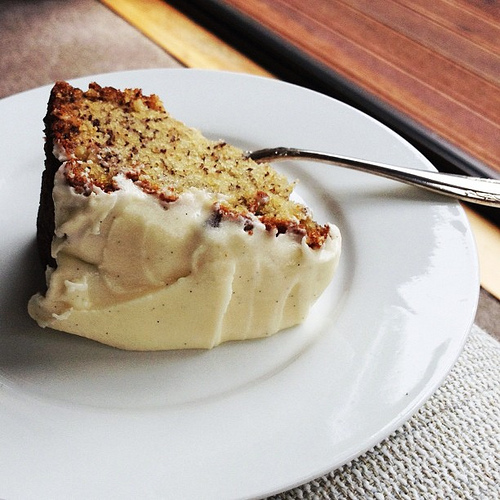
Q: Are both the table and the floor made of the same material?
A: Yes, both the table and the floor are made of wood.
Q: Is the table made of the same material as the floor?
A: Yes, both the table and the floor are made of wood.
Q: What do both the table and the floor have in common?
A: The material, both the table and the floor are wooden.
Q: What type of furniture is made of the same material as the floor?
A: The table is made of the same material as the floor.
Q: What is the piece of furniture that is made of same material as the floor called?
A: The piece of furniture is a table.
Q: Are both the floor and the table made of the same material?
A: Yes, both the floor and the table are made of wood.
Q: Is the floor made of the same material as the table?
A: Yes, both the floor and the table are made of wood.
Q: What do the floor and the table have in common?
A: The material, both the floor and the table are wooden.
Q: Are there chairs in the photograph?
A: No, there are no chairs.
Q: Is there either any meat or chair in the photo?
A: No, there are no chairs or meat.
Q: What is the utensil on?
A: The utensil is on the plate.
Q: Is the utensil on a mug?
A: No, the utensil is on the plate.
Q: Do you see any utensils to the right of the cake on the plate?
A: Yes, there is a utensil to the right of the cake.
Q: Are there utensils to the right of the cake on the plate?
A: Yes, there is a utensil to the right of the cake.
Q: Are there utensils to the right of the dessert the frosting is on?
A: Yes, there is a utensil to the right of the cake.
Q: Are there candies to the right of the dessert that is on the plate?
A: No, there is a utensil to the right of the cake.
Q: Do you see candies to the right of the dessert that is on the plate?
A: No, there is a utensil to the right of the cake.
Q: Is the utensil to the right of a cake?
A: Yes, the utensil is to the right of a cake.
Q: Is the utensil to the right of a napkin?
A: No, the utensil is to the right of a cake.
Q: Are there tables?
A: Yes, there is a table.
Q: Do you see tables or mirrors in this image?
A: Yes, there is a table.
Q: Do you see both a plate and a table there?
A: Yes, there are both a table and a plate.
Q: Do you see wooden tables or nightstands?
A: Yes, there is a wood table.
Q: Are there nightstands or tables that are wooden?
A: Yes, the table is wooden.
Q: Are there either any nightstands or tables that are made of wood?
A: Yes, the table is made of wood.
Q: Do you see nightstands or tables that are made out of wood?
A: Yes, the table is made of wood.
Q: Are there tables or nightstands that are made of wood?
A: Yes, the table is made of wood.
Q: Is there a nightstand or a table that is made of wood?
A: Yes, the table is made of wood.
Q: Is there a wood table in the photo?
A: Yes, there is a wood table.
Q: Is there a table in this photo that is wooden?
A: Yes, there is a table that is wooden.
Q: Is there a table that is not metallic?
A: Yes, there is a wooden table.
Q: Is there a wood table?
A: Yes, there is a table that is made of wood.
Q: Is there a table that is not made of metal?
A: Yes, there is a table that is made of wood.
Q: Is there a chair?
A: No, there are no chairs.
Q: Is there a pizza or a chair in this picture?
A: No, there are no chairs or pizzas.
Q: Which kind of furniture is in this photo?
A: The furniture is a table.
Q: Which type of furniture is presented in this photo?
A: The furniture is a table.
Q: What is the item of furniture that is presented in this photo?
A: The piece of furniture is a table.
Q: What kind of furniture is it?
A: The piece of furniture is a table.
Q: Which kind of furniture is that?
A: That is a table.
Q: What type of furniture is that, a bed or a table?
A: That is a table.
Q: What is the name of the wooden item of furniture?
A: The piece of furniture is a table.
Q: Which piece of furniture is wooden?
A: The piece of furniture is a table.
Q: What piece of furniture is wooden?
A: The piece of furniture is a table.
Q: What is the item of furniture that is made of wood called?
A: The piece of furniture is a table.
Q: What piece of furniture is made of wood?
A: The piece of furniture is a table.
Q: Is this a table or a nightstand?
A: This is a table.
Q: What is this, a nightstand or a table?
A: This is a table.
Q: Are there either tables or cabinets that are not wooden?
A: No, there is a table but it is wooden.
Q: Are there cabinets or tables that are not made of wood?
A: No, there is a table but it is made of wood.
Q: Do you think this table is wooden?
A: Yes, the table is wooden.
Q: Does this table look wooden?
A: Yes, the table is wooden.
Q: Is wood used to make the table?
A: Yes, the table is made of wood.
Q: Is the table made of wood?
A: Yes, the table is made of wood.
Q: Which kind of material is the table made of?
A: The table is made of wood.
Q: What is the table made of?
A: The table is made of wood.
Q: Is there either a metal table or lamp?
A: No, there is a table but it is wooden.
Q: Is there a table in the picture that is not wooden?
A: No, there is a table but it is wooden.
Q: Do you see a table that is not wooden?
A: No, there is a table but it is wooden.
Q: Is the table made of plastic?
A: No, the table is made of wood.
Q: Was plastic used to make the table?
A: No, the table is made of wood.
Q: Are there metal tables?
A: No, there is a table but it is made of wood.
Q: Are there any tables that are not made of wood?
A: No, there is a table but it is made of wood.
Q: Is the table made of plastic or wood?
A: The table is made of wood.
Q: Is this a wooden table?
A: Yes, this is a wooden table.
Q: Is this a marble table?
A: No, this is a wooden table.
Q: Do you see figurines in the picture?
A: No, there are no figurines.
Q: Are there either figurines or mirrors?
A: No, there are no figurines or mirrors.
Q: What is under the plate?
A: The mat is under the plate.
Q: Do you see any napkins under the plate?
A: No, there is a mat under the plate.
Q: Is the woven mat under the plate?
A: Yes, the mat is under the plate.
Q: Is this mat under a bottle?
A: No, the mat is under the plate.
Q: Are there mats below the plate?
A: Yes, there is a mat below the plate.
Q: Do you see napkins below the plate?
A: No, there is a mat below the plate.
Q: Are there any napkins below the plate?
A: No, there is a mat below the plate.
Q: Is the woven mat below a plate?
A: Yes, the mat is below a plate.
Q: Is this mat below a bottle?
A: No, the mat is below a plate.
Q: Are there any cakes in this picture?
A: Yes, there is a cake.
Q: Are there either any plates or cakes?
A: Yes, there is a cake.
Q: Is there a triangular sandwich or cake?
A: Yes, there is a triangular cake.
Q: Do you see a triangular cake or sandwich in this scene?
A: Yes, there is a triangular cake.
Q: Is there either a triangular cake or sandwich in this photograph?
A: Yes, there is a triangular cake.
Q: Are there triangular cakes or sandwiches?
A: Yes, there is a triangular cake.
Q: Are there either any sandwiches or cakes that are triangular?
A: Yes, the cake is triangular.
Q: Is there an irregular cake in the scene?
A: Yes, there is an irregular cake.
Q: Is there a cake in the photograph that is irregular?
A: Yes, there is a cake that is irregular.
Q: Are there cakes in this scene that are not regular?
A: Yes, there is a irregular cake.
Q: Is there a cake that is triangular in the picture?
A: Yes, there is a triangular cake.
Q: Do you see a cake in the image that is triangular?
A: Yes, there is a cake that is triangular.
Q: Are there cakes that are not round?
A: Yes, there is a triangular cake.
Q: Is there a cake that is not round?
A: Yes, there is a triangular cake.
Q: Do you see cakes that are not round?
A: Yes, there is a triangular cake.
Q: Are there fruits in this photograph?
A: No, there are no fruits.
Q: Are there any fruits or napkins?
A: No, there are no fruits or napkins.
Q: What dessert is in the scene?
A: The dessert is a cake.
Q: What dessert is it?
A: The dessert is a cake.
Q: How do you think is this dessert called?
A: This is a cake.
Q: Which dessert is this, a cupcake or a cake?
A: This is a cake.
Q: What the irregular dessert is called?
A: The dessert is a cake.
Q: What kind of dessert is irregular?
A: The dessert is a cake.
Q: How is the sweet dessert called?
A: The dessert is a cake.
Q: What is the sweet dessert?
A: The dessert is a cake.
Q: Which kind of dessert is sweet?
A: The dessert is a cake.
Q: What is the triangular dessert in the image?
A: The dessert is a cake.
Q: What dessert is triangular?
A: The dessert is a cake.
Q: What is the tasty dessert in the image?
A: The dessert is a cake.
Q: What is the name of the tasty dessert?
A: The dessert is a cake.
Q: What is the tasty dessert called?
A: The dessert is a cake.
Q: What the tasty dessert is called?
A: The dessert is a cake.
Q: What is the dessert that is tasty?
A: The dessert is a cake.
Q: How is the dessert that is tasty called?
A: The dessert is a cake.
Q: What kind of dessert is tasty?
A: The dessert is a cake.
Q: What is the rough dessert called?
A: The dessert is a cake.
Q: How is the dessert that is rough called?
A: The dessert is a cake.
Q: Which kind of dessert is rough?
A: The dessert is a cake.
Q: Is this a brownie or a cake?
A: This is a cake.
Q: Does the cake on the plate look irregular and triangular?
A: Yes, the cake is irregular and triangular.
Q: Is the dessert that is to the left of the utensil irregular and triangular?
A: Yes, the cake is irregular and triangular.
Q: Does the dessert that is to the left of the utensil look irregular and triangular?
A: Yes, the cake is irregular and triangular.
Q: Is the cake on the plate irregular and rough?
A: Yes, the cake is irregular and rough.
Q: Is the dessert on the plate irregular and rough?
A: Yes, the cake is irregular and rough.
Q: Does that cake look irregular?
A: Yes, the cake is irregular.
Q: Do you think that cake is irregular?
A: Yes, the cake is irregular.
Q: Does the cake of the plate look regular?
A: No, the cake is irregular.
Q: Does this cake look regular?
A: No, the cake is irregular.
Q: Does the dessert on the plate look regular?
A: No, the cake is irregular.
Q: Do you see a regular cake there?
A: No, there is a cake but it is irregular.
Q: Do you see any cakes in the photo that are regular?
A: No, there is a cake but it is irregular.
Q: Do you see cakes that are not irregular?
A: No, there is a cake but it is irregular.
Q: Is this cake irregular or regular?
A: The cake is irregular.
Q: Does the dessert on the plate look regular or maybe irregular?
A: The cake is irregular.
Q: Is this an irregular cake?
A: Yes, this is an irregular cake.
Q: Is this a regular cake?
A: No, this is an irregular cake.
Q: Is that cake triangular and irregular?
A: Yes, the cake is triangular and irregular.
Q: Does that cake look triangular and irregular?
A: Yes, the cake is triangular and irregular.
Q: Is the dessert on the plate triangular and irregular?
A: Yes, the cake is triangular and irregular.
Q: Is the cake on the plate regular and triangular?
A: No, the cake is triangular but irregular.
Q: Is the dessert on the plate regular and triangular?
A: No, the cake is triangular but irregular.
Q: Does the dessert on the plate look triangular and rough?
A: Yes, the cake is triangular and rough.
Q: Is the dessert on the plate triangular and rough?
A: Yes, the cake is triangular and rough.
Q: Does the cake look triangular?
A: Yes, the cake is triangular.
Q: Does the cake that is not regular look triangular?
A: Yes, the cake is triangular.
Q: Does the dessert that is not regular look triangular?
A: Yes, the cake is triangular.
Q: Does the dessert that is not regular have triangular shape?
A: Yes, the cake is triangular.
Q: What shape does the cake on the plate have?
A: The cake has triangular shape.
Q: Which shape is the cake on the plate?
A: The cake is triangular.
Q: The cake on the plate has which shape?
A: The cake is triangular.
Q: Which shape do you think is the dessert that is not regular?
A: The cake is triangular.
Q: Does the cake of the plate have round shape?
A: No, the cake is triangular.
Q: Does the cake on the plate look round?
A: No, the cake is triangular.